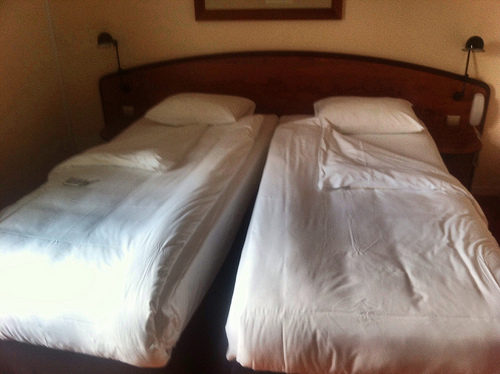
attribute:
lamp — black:
[89, 16, 126, 60]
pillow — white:
[315, 72, 439, 160]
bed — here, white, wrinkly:
[0, 67, 275, 341]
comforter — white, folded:
[74, 119, 177, 174]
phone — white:
[462, 84, 488, 134]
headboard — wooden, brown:
[125, 48, 468, 123]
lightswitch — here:
[439, 107, 465, 135]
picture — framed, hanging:
[186, 9, 338, 27]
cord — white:
[460, 116, 496, 157]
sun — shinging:
[17, 228, 127, 335]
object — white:
[56, 169, 83, 195]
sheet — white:
[373, 130, 421, 163]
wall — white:
[20, 15, 69, 92]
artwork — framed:
[188, 2, 376, 37]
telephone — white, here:
[472, 124, 495, 153]